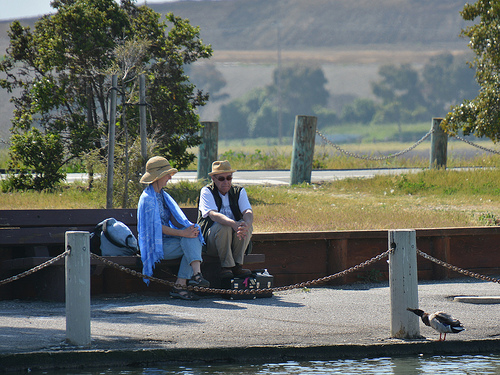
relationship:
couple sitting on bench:
[135, 154, 255, 301] [0, 210, 266, 288]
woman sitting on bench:
[134, 153, 209, 304] [1, 200, 267, 286]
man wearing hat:
[196, 158, 255, 279] [207, 161, 235, 176]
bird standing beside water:
[409, 304, 466, 340] [307, 355, 494, 373]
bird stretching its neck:
[406, 307, 466, 342] [409, 308, 438, 321]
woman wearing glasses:
[134, 153, 209, 304] [216, 167, 234, 184]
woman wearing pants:
[134, 153, 209, 304] [207, 220, 252, 266]